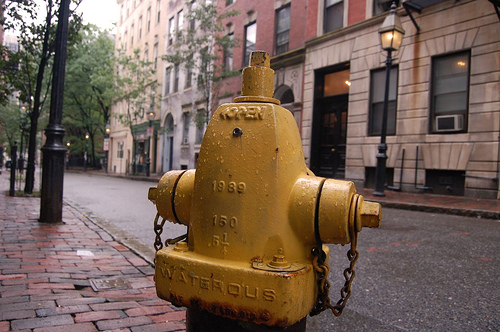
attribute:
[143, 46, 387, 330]
fire hydrant — yellow, rusty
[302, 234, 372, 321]
chain — yellow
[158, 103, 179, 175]
doorway — arched, stone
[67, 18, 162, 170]
trees — green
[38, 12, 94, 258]
pole — black, tall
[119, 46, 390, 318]
hydrant — fire, yellow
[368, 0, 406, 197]
street light — lit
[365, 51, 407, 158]
pole — black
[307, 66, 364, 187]
door — large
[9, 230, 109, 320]
airplane — uneven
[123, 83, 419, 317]
hydrant — yellow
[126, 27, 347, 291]
hydrant — fire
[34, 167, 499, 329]
street — deserted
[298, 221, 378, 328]
chain — rusty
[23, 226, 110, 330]
sidewalk — paved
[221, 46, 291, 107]
fire hydrant — yellow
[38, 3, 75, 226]
pole — metal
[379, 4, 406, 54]
light — on